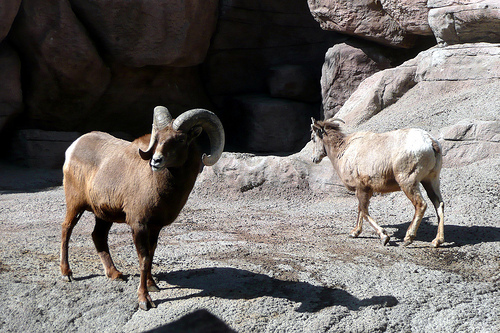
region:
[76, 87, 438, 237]
two animals on the ground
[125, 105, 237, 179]
head of the animal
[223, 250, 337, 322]
shadow on the ground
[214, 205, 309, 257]
silver rock on the ground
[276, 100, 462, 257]
animal on the ground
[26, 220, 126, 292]
back legs of the animal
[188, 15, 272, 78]
shadow in the background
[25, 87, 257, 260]
brown fur on animal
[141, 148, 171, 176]
nose of the animal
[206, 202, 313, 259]
rocks on the ground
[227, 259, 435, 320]
The ground is made of rock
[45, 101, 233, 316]
The animal is called a ram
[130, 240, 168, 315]
The front legs of the ram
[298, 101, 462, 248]
The animal is called a goat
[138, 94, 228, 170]
The horns on the ram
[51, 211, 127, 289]
The back legs of the ram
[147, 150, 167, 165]
The nose of the ram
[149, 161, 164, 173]
The mouth of the ram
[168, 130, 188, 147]
The eye of the ram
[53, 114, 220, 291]
The ram is the color brown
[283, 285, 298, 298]
part of a shade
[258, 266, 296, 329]
ppart of a shade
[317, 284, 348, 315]
part of a shade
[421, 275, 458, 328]
part of a ground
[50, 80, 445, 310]
two rams standing together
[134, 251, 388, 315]
ram's shadow on the gravel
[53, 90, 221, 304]
brow ram with gray horns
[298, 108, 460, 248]
whit ram with brown on his neck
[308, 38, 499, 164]
rocks behind white ram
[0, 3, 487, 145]
rock wall on backside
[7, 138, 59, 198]
shadow of the rock wall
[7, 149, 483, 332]
gravel rams are standing on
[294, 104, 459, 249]
white ram walking away from other ram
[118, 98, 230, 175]
gray horns of brown ram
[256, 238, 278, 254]
Gray ground in the mountains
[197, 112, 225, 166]
Left horn of the goat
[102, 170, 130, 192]
Brown skin of the goat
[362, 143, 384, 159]
White and brown skin of the goat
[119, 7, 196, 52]
Enormous brown rock in the back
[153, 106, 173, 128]
Gray right horn of the goat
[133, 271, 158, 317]
Right front foot of the goat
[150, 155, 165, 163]
Gray nose of the goat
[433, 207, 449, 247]
Back right foot of the second goat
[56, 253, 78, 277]
Back right foot of the first goat